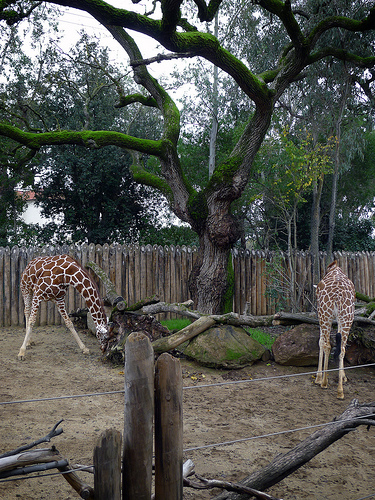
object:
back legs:
[19, 267, 37, 333]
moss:
[74, 127, 99, 148]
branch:
[162, 97, 183, 158]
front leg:
[321, 320, 331, 380]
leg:
[56, 298, 84, 350]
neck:
[75, 276, 109, 325]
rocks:
[271, 317, 320, 364]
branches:
[139, 300, 374, 330]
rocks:
[180, 321, 270, 370]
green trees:
[169, 109, 251, 215]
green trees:
[247, 123, 339, 274]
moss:
[135, 171, 165, 187]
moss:
[189, 163, 240, 186]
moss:
[0, 122, 30, 143]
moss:
[163, 92, 178, 130]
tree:
[295, 87, 322, 250]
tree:
[319, 78, 375, 248]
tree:
[53, 39, 136, 239]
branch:
[6, 110, 156, 158]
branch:
[305, 42, 371, 76]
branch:
[135, 22, 269, 107]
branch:
[278, 18, 306, 64]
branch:
[126, 152, 165, 195]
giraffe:
[14, 251, 114, 362]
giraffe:
[310, 227, 356, 403]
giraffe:
[14, 241, 115, 367]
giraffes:
[17, 256, 109, 363]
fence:
[3, 243, 375, 329]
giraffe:
[309, 258, 357, 399]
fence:
[1, 325, 374, 498]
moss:
[125, 131, 163, 148]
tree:
[0, 0, 374, 326]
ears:
[96, 324, 107, 334]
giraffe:
[307, 258, 349, 397]